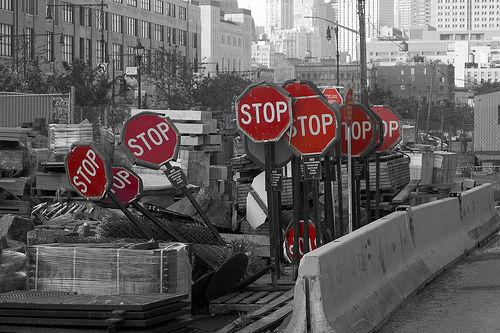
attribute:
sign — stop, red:
[219, 77, 316, 208]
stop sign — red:
[118, 107, 179, 169]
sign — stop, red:
[64, 142, 110, 199]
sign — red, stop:
[105, 160, 140, 206]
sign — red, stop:
[235, 86, 300, 144]